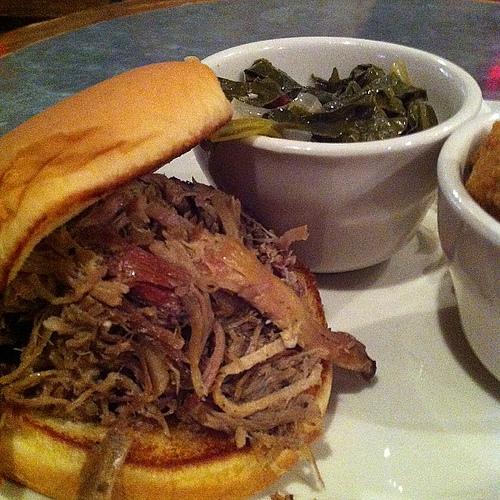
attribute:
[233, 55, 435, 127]
vegetable — green, piece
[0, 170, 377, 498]
meat — cooked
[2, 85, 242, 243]
bread — brown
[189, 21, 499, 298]
bowl — white, shiny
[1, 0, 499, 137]
table — blue 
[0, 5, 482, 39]
table — blue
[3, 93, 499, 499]
plate — white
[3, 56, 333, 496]
bun — toasted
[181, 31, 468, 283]
bowl — white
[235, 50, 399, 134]
vegetable — green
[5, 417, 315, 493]
bun — toasted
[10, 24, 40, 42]
edge — wooden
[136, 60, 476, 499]
plate — white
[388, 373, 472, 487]
surface — white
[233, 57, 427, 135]
vegetable — green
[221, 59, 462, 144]
vegetable — green